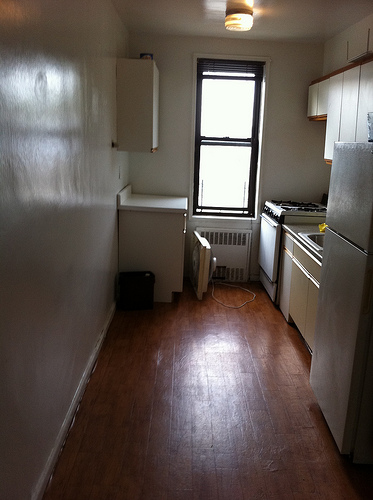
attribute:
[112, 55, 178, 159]
cabinet — white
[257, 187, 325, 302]
stove — in kitchen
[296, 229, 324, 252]
sink — grey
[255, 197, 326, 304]
range — white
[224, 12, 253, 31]
light — yellow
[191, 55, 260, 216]
frame — brown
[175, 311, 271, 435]
floor — brown, wooden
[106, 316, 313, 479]
floor — brown, wooden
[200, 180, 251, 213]
guard — children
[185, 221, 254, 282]
radiator — white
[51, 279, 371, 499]
wooden floor — brown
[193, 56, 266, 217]
frame — black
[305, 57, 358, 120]
border — brown